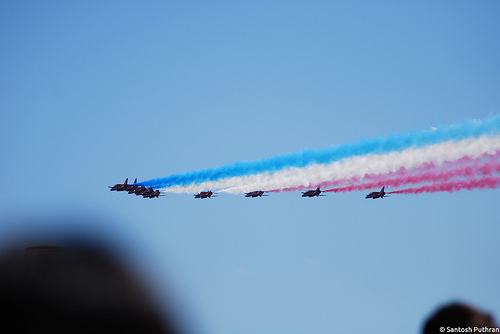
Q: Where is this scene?
A: An air show.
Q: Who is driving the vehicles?
A: Pilots.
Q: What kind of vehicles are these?
A: Jets.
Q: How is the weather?
A: Sunny.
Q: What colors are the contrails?
A: Red, white, and blue.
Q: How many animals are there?
A: None.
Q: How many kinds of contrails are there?
A: Three.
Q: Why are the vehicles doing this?
A: For entertainment.